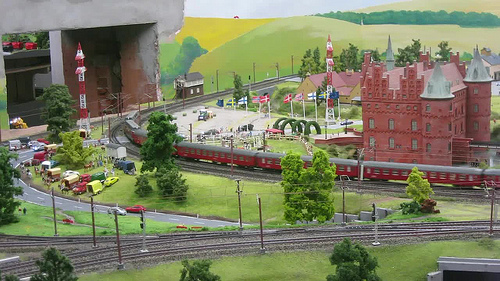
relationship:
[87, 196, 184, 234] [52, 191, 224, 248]
cars on road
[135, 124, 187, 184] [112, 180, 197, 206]
trees on hill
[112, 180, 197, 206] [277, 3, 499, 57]
hill in background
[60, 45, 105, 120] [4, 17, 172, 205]
tower on left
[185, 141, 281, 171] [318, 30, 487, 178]
train by bulidings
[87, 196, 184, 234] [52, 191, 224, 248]
cars by road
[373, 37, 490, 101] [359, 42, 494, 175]
towers of building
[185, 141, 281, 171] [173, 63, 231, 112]
train has booth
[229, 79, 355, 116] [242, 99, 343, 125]
flags on posts